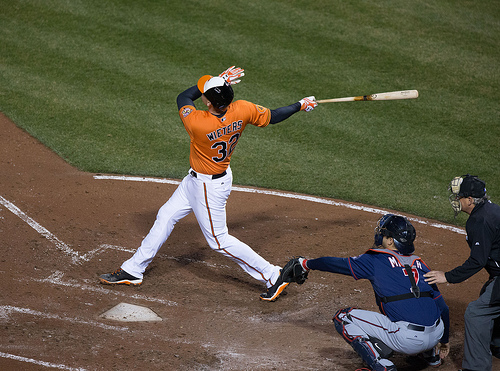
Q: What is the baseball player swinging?
A: Bat.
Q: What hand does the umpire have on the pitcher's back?
A: Left.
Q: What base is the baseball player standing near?
A: Home.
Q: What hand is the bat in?
A: Right.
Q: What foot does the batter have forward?
A: Right.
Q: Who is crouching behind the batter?
A: Catcher.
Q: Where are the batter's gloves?
A: On his hands.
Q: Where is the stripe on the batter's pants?
A: Side.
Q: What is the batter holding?
A: A bat.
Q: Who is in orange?
A: A batter.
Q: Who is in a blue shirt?
A: A catcher.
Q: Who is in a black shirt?
A: Umpire.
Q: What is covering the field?
A: Grass.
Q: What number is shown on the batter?
A: 32.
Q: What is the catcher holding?
A: A mitt.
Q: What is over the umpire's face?
A: A mask.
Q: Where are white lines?
A: On the dirt.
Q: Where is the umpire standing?
A: Behind the catcher.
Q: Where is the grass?
A: On the field.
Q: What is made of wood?
A: Bat.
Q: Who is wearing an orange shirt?
A: Batter.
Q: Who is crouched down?
A: The catcher.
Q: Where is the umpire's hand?
A: On catcher's back.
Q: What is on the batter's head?
A: A baseball cap.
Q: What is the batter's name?
A: Wieters.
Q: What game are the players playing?
A: Baseball.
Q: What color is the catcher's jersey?
A: Blue.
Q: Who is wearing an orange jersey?
A: The batter.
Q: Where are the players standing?
A: Around home plate.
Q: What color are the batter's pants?
A: White.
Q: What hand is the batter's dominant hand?
A: His left hand.